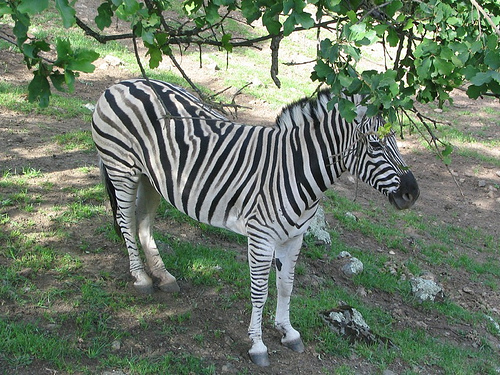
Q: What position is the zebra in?
A: Standing.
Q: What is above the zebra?
A: Leaves.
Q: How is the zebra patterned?
A: Stripes.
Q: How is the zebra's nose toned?
A: Dark.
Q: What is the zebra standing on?
A: Patches of dirt.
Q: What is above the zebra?
A: Branches.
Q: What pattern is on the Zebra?
A: Stripes.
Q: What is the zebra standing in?
A: The grass.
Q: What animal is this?
A: A zebra.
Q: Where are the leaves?
A: Above the animal.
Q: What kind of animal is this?
A: A mammal.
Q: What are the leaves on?
A: The tree.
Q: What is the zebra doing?
A: Standing.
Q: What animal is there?
A: Zebra.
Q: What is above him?
A: Tree branch.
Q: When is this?
A: Daytime.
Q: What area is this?
A: Wooded area.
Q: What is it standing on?
A: Dirt and grass.